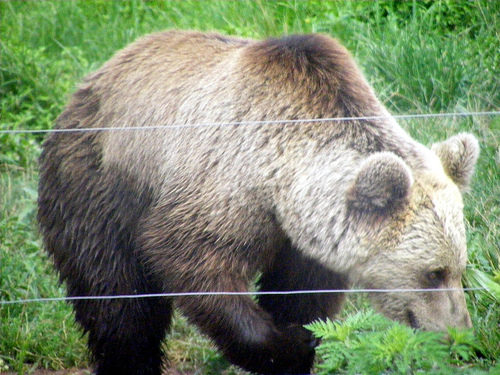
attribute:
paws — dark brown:
[239, 304, 329, 373]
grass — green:
[1, 10, 104, 103]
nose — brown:
[425, 303, 475, 350]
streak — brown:
[238, 33, 376, 145]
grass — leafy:
[341, 292, 495, 371]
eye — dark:
[422, 262, 443, 289]